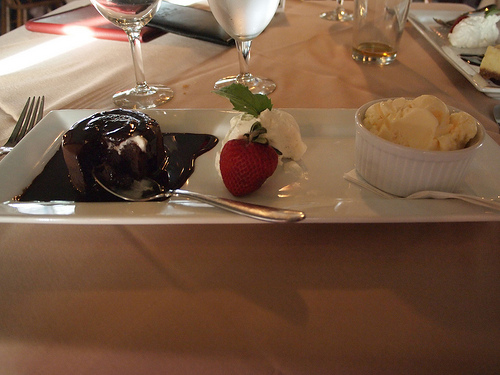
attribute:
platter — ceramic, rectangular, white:
[0, 109, 500, 225]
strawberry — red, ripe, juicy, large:
[219, 121, 282, 197]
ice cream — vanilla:
[363, 94, 477, 151]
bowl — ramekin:
[355, 98, 486, 198]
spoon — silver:
[91, 167, 306, 222]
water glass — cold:
[207, 1, 281, 96]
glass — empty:
[351, 0, 412, 66]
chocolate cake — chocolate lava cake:
[62, 108, 166, 194]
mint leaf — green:
[211, 83, 273, 119]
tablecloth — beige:
[0, 0, 499, 374]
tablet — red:
[25, 3, 168, 43]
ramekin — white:
[354, 96, 486, 197]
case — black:
[146, 0, 237, 46]